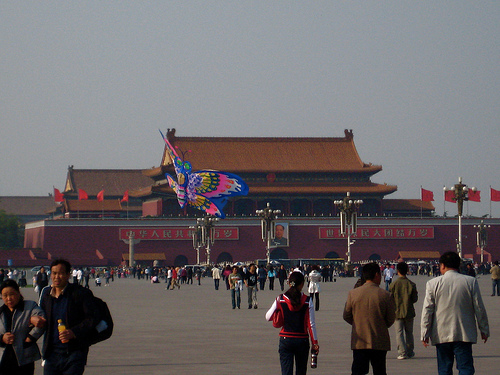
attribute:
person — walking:
[223, 270, 242, 305]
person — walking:
[343, 262, 393, 372]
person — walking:
[422, 253, 490, 373]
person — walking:
[265, 274, 318, 374]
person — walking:
[3, 264, 113, 374]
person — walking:
[340, 261, 397, 373]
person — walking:
[386, 261, 418, 361]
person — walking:
[261, 270, 321, 373]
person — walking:
[29, 257, 95, 372]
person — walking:
[168, 265, 181, 294]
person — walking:
[37, 260, 106, 372]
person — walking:
[388, 260, 418, 357]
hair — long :
[286, 270, 303, 312]